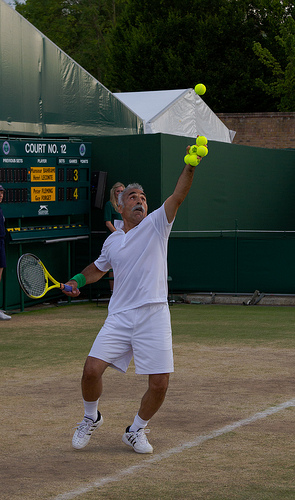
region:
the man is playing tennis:
[59, 136, 191, 361]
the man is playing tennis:
[24, 236, 70, 310]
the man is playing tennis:
[45, 127, 261, 437]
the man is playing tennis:
[76, 177, 238, 313]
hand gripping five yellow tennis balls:
[176, 130, 215, 171]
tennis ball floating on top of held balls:
[183, 79, 211, 168]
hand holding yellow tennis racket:
[14, 239, 79, 298]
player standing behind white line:
[68, 177, 189, 485]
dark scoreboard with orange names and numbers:
[0, 133, 88, 230]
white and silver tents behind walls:
[1, 3, 237, 140]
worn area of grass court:
[6, 333, 285, 493]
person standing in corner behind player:
[94, 130, 158, 227]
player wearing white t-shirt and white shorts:
[83, 179, 178, 370]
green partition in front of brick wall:
[141, 106, 289, 298]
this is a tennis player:
[49, 110, 232, 423]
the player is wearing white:
[77, 207, 228, 424]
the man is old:
[75, 169, 188, 293]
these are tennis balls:
[130, 71, 255, 241]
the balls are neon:
[164, 34, 252, 216]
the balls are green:
[154, 82, 238, 208]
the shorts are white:
[53, 300, 200, 388]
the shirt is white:
[106, 243, 167, 293]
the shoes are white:
[50, 373, 145, 466]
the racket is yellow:
[13, 237, 104, 340]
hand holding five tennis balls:
[183, 135, 209, 168]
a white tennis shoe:
[121, 426, 156, 454]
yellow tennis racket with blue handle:
[16, 253, 77, 298]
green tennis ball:
[193, 83, 206, 95]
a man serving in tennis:
[58, 139, 207, 453]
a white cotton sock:
[80, 397, 100, 420]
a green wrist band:
[70, 273, 88, 286]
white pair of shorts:
[82, 303, 176, 375]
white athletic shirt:
[92, 203, 185, 314]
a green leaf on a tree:
[112, 38, 117, 44]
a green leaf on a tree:
[182, 38, 189, 45]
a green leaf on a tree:
[280, 103, 281, 107]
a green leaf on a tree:
[214, 98, 221, 105]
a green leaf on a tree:
[90, 19, 98, 24]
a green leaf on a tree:
[144, 48, 148, 55]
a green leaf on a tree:
[212, 34, 218, 39]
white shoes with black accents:
[67, 410, 153, 457]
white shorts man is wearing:
[87, 308, 179, 375]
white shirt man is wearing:
[100, 211, 172, 311]